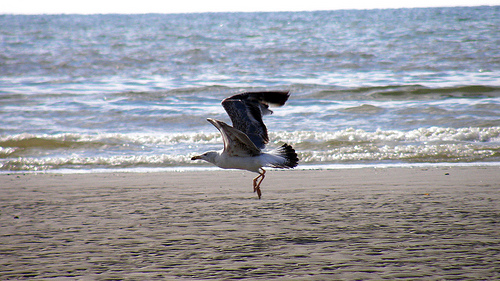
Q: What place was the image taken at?
A: It was taken at the beach.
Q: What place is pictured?
A: It is a beach.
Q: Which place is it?
A: It is a beach.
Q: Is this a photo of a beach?
A: Yes, it is showing a beach.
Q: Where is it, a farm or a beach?
A: It is a beach.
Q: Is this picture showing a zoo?
A: No, the picture is showing a beach.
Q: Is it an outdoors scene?
A: Yes, it is outdoors.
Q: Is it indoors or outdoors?
A: It is outdoors.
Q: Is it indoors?
A: No, it is outdoors.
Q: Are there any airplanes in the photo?
A: No, there are no airplanes.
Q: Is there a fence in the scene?
A: No, there are no fences.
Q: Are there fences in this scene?
A: No, there are no fences.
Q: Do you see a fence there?
A: No, there are no fences.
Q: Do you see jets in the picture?
A: No, there are no jets.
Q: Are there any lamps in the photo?
A: No, there are no lamps.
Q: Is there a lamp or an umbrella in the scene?
A: No, there are no lamps or umbrellas.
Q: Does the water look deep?
A: Yes, the water is deep.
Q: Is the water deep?
A: Yes, the water is deep.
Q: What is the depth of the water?
A: The water is deep.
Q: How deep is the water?
A: The water is deep.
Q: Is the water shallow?
A: No, the water is deep.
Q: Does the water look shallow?
A: No, the water is deep.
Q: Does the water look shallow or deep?
A: The water is deep.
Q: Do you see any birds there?
A: Yes, there is a bird.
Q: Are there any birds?
A: Yes, there is a bird.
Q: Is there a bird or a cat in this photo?
A: Yes, there is a bird.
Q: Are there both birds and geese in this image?
A: No, there is a bird but no geese.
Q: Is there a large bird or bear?
A: Yes, there is a large bird.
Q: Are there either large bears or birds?
A: Yes, there is a large bird.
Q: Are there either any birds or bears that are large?
A: Yes, the bird is large.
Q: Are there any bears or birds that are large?
A: Yes, the bird is large.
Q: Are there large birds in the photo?
A: Yes, there is a large bird.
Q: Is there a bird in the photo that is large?
A: Yes, there is a bird that is large.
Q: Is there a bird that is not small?
A: Yes, there is a large bird.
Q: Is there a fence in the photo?
A: No, there are no fences.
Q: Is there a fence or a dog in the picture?
A: No, there are no fences or dogs.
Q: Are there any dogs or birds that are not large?
A: No, there is a bird but it is large.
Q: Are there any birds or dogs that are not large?
A: No, there is a bird but it is large.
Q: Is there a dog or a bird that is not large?
A: No, there is a bird but it is large.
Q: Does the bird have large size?
A: Yes, the bird is large.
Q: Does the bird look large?
A: Yes, the bird is large.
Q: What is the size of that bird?
A: The bird is large.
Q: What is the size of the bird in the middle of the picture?
A: The bird is large.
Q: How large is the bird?
A: The bird is large.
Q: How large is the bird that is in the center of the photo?
A: The bird is large.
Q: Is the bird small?
A: No, the bird is large.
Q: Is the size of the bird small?
A: No, the bird is large.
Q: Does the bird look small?
A: No, the bird is large.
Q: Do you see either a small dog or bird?
A: No, there is a bird but it is large.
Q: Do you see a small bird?
A: No, there is a bird but it is large.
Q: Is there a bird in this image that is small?
A: No, there is a bird but it is large.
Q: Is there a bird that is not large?
A: No, there is a bird but it is large.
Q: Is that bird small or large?
A: The bird is large.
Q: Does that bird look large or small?
A: The bird is large.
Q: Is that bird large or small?
A: The bird is large.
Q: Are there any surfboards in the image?
A: No, there are no surfboards.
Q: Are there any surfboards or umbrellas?
A: No, there are no surfboards or umbrellas.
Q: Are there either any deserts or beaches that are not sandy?
A: No, there is a beach but it is sandy.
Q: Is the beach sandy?
A: Yes, the beach is sandy.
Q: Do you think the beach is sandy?
A: Yes, the beach is sandy.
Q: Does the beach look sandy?
A: Yes, the beach is sandy.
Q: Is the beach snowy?
A: No, the beach is sandy.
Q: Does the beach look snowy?
A: No, the beach is sandy.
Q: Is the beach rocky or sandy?
A: The beach is sandy.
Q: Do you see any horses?
A: No, there are no horses.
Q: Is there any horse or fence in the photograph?
A: No, there are no horses or fences.